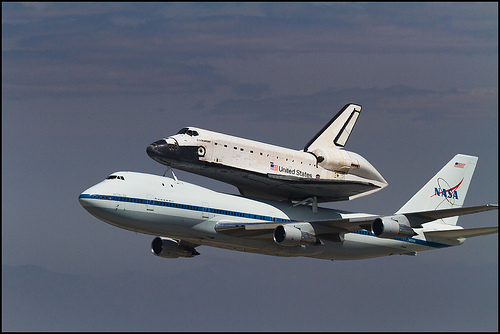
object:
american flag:
[271, 165, 278, 171]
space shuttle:
[147, 104, 389, 214]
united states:
[279, 166, 313, 179]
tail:
[391, 152, 477, 226]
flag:
[454, 162, 465, 168]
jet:
[76, 152, 499, 262]